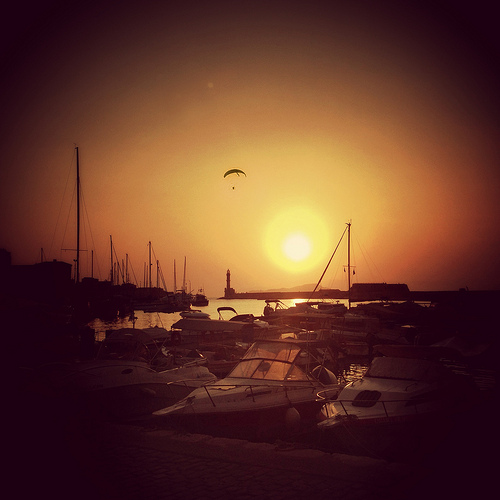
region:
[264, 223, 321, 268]
The sun in the sky.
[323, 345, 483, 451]
The boat on the right.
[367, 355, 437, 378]
The window of the boat on the right.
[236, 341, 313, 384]
The window of the boat in the middle.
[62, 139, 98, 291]
The tallest sail pole on the right.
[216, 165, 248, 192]
The parasail in the air.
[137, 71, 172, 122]
white clouds in blue sky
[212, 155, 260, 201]
The bird is flying in the sky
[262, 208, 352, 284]
The sun is in the sky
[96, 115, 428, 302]
The sky is orange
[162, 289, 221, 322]
The boat is in the water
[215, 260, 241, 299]
The building is tall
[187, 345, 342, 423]
a boat on the water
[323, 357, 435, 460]
a boat on the water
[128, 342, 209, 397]
a boat on the water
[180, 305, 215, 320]
a boat on the water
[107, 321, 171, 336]
a boat on the water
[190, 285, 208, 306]
a boat on the water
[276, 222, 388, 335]
a boat on the water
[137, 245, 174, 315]
a boat on the water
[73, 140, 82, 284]
black mast silhouette by the ship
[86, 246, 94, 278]
black mast silhouette by the ship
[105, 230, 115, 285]
black mast silhouette by the ship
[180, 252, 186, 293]
black mast silhouette by the ship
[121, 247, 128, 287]
black mast silhouette by the ship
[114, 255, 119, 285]
black mast silhouette by the ship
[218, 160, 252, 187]
para sail in the sky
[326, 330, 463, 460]
white boat in the dock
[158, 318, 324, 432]
white boat in the dock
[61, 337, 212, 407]
white boat in the dock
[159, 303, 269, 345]
white boat in the dock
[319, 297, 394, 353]
white boat in the dock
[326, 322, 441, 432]
white boat in the dock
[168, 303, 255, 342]
white boat in the dock